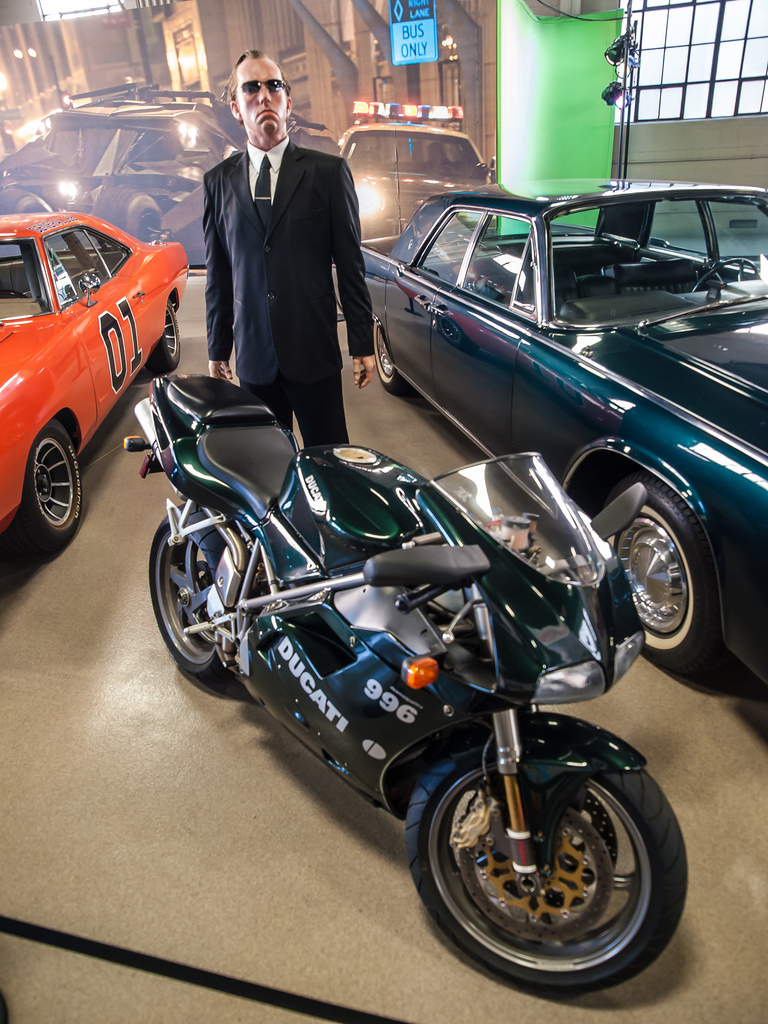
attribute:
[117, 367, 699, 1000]
motorcycle — black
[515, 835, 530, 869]
stripe — red, small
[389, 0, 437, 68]
signage — blue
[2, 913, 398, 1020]
stripe — black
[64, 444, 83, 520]
letterings — white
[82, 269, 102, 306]
side mirror — small, shiny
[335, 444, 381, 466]
round — gold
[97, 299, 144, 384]
numbers — black and white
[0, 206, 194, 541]
car — red, orange and black, General Lee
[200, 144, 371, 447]
suit — black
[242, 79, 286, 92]
sunglasses — black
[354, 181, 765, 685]
car — black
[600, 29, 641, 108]
lights — large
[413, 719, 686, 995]
wheel — front wheel